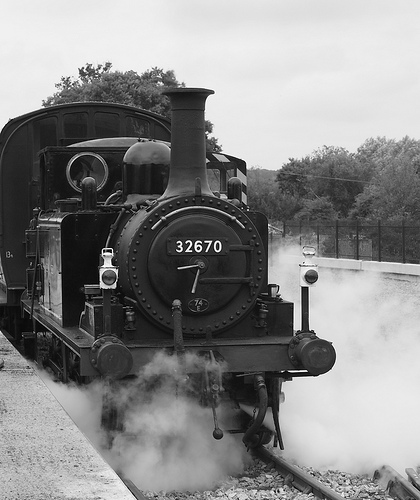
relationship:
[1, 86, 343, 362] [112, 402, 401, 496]
platform near tracks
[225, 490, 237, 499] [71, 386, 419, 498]
pebbles are on tracks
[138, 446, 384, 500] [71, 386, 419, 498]
pebbles are on tracks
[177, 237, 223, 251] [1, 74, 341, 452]
number on train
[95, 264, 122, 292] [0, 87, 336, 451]
headlight on black train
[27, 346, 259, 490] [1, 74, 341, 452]
steam coming from train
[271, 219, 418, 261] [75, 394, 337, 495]
fence near tracks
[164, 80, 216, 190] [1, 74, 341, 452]
smoke stack on train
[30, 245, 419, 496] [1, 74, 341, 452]
smoke stack on train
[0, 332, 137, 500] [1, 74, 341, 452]
platform near train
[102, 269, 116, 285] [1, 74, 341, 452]
headlight on train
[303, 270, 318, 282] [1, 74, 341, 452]
headlight on train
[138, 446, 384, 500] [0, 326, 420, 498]
pebbles near tracks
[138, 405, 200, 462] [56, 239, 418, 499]
part of smoke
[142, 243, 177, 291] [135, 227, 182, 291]
part of metal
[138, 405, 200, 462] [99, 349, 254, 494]
part of smoke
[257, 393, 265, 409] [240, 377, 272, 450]
part of pipe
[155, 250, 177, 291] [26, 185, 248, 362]
part of metal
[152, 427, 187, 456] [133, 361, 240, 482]
part of smoke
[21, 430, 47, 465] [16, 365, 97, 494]
part of rail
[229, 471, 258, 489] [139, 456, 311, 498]
part of ground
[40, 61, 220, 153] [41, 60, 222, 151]
leaves on tree